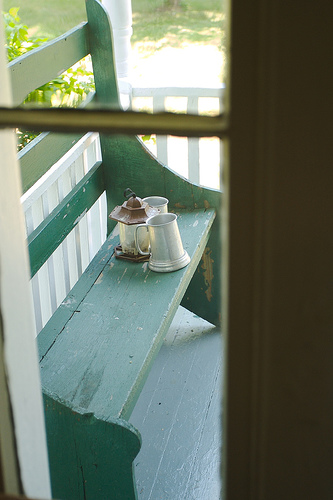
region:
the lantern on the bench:
[110, 188, 158, 268]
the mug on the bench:
[131, 208, 192, 274]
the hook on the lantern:
[124, 186, 136, 200]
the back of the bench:
[3, 8, 104, 264]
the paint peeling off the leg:
[199, 249, 216, 300]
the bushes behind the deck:
[1, 9, 89, 155]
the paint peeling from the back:
[57, 185, 92, 230]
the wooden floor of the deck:
[156, 366, 216, 492]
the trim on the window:
[0, 102, 234, 151]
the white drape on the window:
[1, 31, 52, 496]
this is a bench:
[0, 71, 228, 492]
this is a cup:
[132, 204, 198, 299]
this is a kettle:
[104, 187, 152, 265]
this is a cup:
[129, 183, 174, 241]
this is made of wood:
[140, 402, 201, 485]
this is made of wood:
[146, 327, 233, 407]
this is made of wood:
[39, 355, 145, 468]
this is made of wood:
[59, 276, 147, 343]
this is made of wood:
[59, 391, 147, 487]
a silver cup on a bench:
[132, 210, 188, 273]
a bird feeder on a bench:
[110, 193, 152, 261]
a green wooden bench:
[8, 100, 221, 494]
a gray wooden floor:
[153, 359, 208, 475]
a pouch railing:
[138, 85, 220, 98]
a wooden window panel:
[0, 105, 223, 132]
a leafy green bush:
[0, 1, 70, 51]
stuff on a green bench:
[105, 186, 180, 273]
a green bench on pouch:
[12, 156, 229, 492]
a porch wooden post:
[116, 0, 145, 88]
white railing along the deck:
[11, 79, 267, 361]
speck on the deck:
[154, 397, 164, 407]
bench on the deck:
[3, 0, 247, 494]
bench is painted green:
[2, 1, 225, 498]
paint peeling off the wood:
[201, 246, 217, 308]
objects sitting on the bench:
[105, 174, 188, 276]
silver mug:
[124, 210, 189, 277]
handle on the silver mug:
[131, 222, 151, 255]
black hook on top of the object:
[122, 185, 138, 201]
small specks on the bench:
[124, 349, 135, 366]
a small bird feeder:
[109, 188, 160, 264]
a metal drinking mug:
[133, 212, 191, 271]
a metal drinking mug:
[140, 195, 168, 212]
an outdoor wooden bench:
[5, 0, 222, 498]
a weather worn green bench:
[4, 0, 221, 499]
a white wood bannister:
[134, 83, 226, 96]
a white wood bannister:
[20, 129, 97, 214]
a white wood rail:
[152, 96, 167, 166]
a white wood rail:
[186, 96, 200, 183]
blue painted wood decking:
[128, 302, 222, 497]